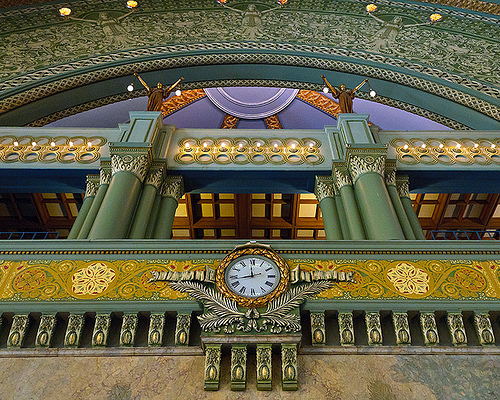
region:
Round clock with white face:
[222, 253, 281, 300]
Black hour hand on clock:
[248, 263, 254, 274]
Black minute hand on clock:
[232, 270, 260, 280]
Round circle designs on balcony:
[175, 124, 325, 167]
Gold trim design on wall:
[5, 259, 185, 294]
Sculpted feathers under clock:
[172, 279, 336, 329]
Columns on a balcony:
[10, 310, 194, 344]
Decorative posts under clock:
[201, 341, 303, 390]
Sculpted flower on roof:
[53, 5, 75, 18]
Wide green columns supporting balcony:
[309, 157, 420, 242]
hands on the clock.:
[183, 199, 413, 381]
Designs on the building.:
[51, 197, 288, 376]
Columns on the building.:
[51, 102, 332, 320]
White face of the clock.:
[185, 231, 345, 352]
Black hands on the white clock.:
[192, 221, 352, 349]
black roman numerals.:
[202, 222, 325, 342]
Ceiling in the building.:
[61, 54, 477, 170]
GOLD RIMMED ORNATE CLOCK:
[213, 245, 293, 312]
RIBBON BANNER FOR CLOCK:
[140, 265, 216, 286]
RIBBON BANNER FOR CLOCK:
[288, 265, 358, 283]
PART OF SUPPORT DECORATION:
[261, 281, 362, 333]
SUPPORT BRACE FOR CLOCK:
[200, 343, 222, 393]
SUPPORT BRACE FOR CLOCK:
[226, 342, 251, 394]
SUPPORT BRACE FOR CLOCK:
[253, 343, 275, 394]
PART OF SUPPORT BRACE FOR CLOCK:
[278, 342, 305, 391]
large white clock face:
[214, 237, 289, 310]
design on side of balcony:
[59, 260, 125, 299]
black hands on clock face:
[235, 264, 265, 283]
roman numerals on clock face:
[226, 261, 244, 288]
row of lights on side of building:
[167, 133, 334, 154]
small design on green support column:
[102, 153, 152, 181]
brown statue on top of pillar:
[325, 73, 367, 110]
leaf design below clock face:
[167, 277, 329, 339]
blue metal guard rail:
[0, 227, 65, 242]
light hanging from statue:
[123, 73, 146, 85]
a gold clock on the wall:
[218, 251, 283, 301]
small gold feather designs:
[156, 270, 340, 332]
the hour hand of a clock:
[242, 258, 259, 278]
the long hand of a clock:
[238, 274, 261, 281]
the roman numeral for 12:
[246, 259, 259, 266]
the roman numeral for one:
[257, 251, 267, 268]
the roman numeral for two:
[264, 264, 273, 270]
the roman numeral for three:
[267, 270, 282, 280]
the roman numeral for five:
[255, 286, 270, 297]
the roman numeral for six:
[250, 285, 260, 295]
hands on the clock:
[242, 262, 260, 280]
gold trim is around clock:
[222, 246, 292, 300]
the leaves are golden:
[187, 278, 303, 330]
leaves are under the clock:
[207, 238, 303, 327]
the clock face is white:
[229, 250, 285, 302]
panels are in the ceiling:
[174, 192, 484, 233]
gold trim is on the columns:
[80, 152, 181, 212]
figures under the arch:
[137, 68, 373, 118]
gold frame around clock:
[216, 244, 288, 308]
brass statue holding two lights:
[126, 68, 186, 114]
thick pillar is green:
[64, 136, 184, 239]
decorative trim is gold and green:
[1, 258, 498, 298]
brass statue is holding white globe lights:
[318, 71, 375, 114]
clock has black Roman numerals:
[215, 247, 290, 308]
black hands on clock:
[214, 243, 289, 307]